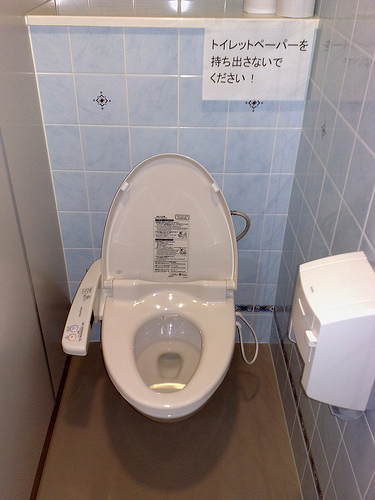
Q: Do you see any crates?
A: No, there are no crates.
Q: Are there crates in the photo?
A: No, there are no crates.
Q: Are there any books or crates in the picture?
A: No, there are no crates or books.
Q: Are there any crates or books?
A: No, there are no crates or books.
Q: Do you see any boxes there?
A: No, there are no boxes.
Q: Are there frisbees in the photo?
A: No, there are no frisbees.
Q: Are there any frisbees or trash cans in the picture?
A: No, there are no frisbees or trash cans.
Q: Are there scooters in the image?
A: No, there are no scooters.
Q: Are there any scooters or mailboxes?
A: No, there are no scooters or mailboxes.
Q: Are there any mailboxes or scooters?
A: No, there are no scooters or mailboxes.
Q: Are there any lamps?
A: No, there are no lamps.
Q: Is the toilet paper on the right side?
A: Yes, the toilet paper is on the right of the image.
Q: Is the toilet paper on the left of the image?
A: No, the toilet paper is on the right of the image.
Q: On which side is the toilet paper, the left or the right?
A: The toilet paper is on the right of the image.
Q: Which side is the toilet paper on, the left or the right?
A: The toilet paper is on the right of the image.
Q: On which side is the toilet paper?
A: The toilet paper is on the right of the image.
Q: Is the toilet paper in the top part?
A: Yes, the toilet paper is in the top of the image.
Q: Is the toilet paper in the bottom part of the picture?
A: No, the toilet paper is in the top of the image.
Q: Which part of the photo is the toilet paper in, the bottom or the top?
A: The toilet paper is in the top of the image.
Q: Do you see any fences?
A: No, there are no fences.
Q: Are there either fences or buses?
A: No, there are no fences or buses.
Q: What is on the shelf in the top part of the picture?
A: The sign is on the shelf.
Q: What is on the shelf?
A: The sign is on the shelf.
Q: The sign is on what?
A: The sign is on the shelf.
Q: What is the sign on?
A: The sign is on the shelf.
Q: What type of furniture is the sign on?
A: The sign is on the shelf.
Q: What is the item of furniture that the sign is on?
A: The piece of furniture is a shelf.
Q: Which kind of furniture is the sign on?
A: The sign is on the shelf.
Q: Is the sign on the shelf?
A: Yes, the sign is on the shelf.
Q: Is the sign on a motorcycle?
A: No, the sign is on the shelf.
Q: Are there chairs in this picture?
A: No, there are no chairs.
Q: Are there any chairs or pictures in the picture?
A: No, there are no chairs or pictures.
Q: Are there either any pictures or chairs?
A: No, there are no chairs or pictures.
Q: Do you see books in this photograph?
A: No, there are no books.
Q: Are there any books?
A: No, there are no books.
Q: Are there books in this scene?
A: No, there are no books.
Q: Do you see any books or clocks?
A: No, there are no books or clocks.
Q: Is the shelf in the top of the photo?
A: Yes, the shelf is in the top of the image.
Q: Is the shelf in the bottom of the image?
A: No, the shelf is in the top of the image.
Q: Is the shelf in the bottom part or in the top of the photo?
A: The shelf is in the top of the image.